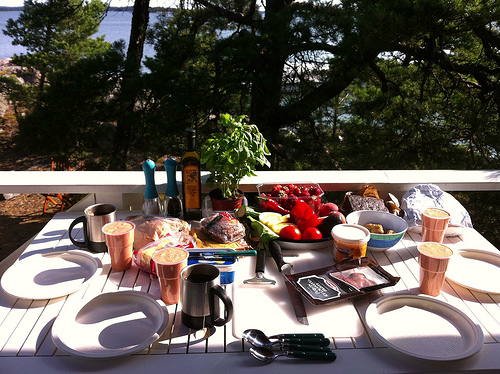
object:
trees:
[109, 0, 151, 172]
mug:
[66, 202, 124, 252]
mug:
[178, 261, 233, 329]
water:
[0, 6, 500, 160]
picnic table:
[0, 212, 500, 373]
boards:
[1, 300, 50, 355]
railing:
[0, 168, 500, 193]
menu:
[283, 256, 406, 304]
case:
[209, 208, 241, 217]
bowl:
[272, 233, 338, 251]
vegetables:
[278, 224, 303, 243]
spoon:
[247, 345, 339, 363]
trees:
[0, 0, 129, 152]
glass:
[109, 237, 124, 251]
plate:
[51, 289, 170, 360]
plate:
[1, 250, 101, 300]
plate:
[440, 246, 500, 295]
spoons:
[244, 332, 332, 348]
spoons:
[241, 329, 327, 338]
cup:
[101, 219, 135, 272]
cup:
[148, 245, 192, 304]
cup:
[415, 238, 456, 297]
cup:
[420, 207, 452, 246]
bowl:
[255, 182, 325, 212]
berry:
[311, 185, 323, 196]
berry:
[300, 191, 310, 198]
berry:
[287, 192, 298, 203]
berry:
[272, 185, 280, 194]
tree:
[191, 0, 500, 171]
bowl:
[364, 293, 485, 363]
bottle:
[182, 125, 201, 224]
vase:
[207, 185, 244, 210]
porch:
[0, 150, 500, 374]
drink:
[152, 247, 189, 265]